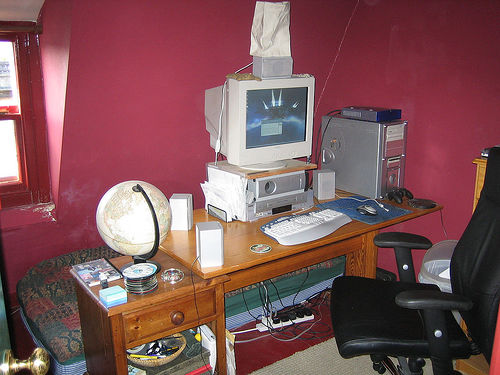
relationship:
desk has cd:
[68, 190, 445, 373] [249, 241, 270, 254]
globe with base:
[94, 180, 172, 254] [123, 253, 160, 272]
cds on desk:
[123, 261, 161, 294] [68, 190, 445, 373]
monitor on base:
[198, 77, 321, 166] [241, 160, 288, 172]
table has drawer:
[81, 242, 223, 370] [116, 282, 213, 339]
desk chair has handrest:
[321, 147, 499, 369] [394, 285, 477, 315]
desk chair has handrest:
[321, 147, 499, 369] [370, 228, 435, 252]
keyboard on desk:
[260, 207, 348, 247] [222, 213, 266, 260]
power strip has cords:
[252, 309, 316, 333] [244, 282, 306, 312]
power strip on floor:
[254, 313, 284, 331] [232, 323, 312, 367]